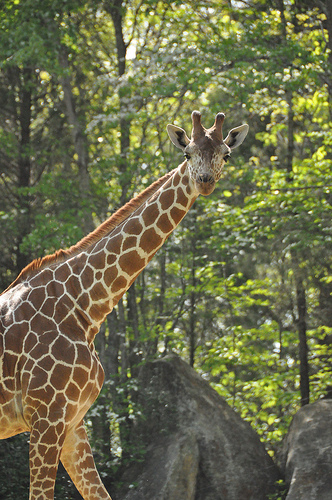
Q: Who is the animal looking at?
A: Photographer.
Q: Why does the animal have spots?
A: Camouflage.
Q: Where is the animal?
A: Jungle.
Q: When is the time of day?
A: Daytime.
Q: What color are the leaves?
A: Green.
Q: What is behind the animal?
A: Rocks.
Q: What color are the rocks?
A: Grey.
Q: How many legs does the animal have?
A: Four.